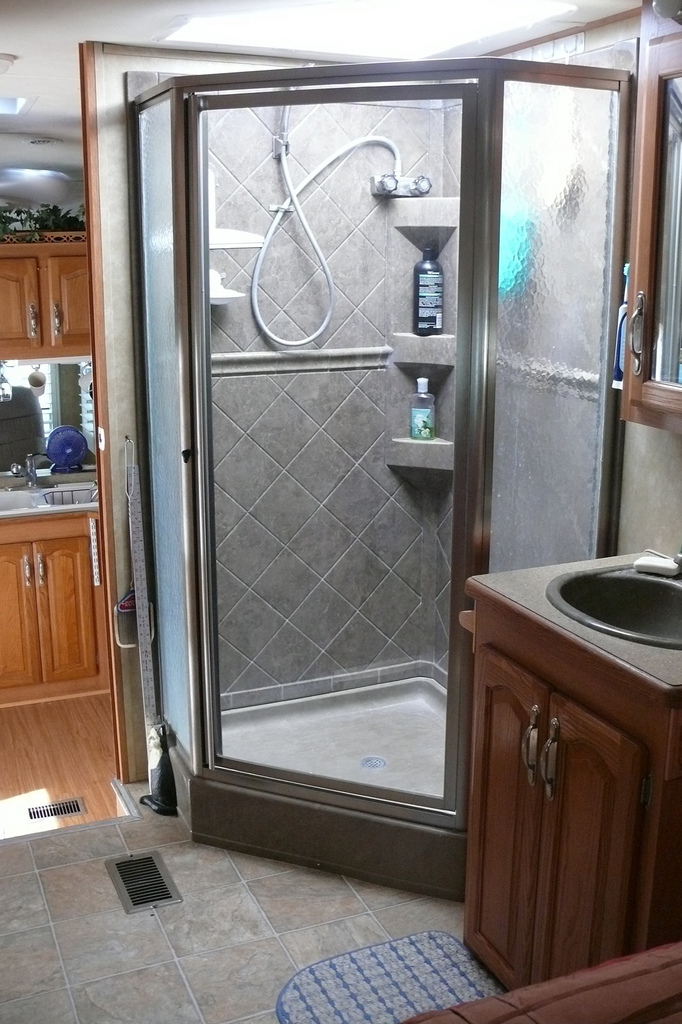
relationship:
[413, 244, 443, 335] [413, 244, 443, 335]
bottle of bottle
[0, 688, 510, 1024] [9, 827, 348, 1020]
bathroom floor on bathroom floor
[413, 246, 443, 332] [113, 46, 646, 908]
bottle in shower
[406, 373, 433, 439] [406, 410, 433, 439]
bottle with label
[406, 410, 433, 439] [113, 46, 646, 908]
label in shower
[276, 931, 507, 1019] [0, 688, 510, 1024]
mat on bathroom floor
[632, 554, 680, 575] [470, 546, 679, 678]
soap on sink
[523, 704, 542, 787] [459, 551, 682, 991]
handle on base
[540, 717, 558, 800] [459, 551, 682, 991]
handle on base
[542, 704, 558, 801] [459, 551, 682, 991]
handle on base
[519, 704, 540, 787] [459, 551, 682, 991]
handle on base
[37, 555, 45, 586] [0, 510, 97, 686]
handle on cabinets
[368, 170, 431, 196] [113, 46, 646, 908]
knobs in shower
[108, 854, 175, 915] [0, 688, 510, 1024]
vent on bathroom floor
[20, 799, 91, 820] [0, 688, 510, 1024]
vent on bathroom floor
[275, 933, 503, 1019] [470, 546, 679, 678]
mat in front of sink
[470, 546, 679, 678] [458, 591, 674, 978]
sink has base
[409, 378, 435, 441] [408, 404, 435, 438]
bottle has label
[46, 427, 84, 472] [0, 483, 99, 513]
fan above sink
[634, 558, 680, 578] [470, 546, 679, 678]
soap on sink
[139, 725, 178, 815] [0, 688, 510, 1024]
decoration on bathroom floor